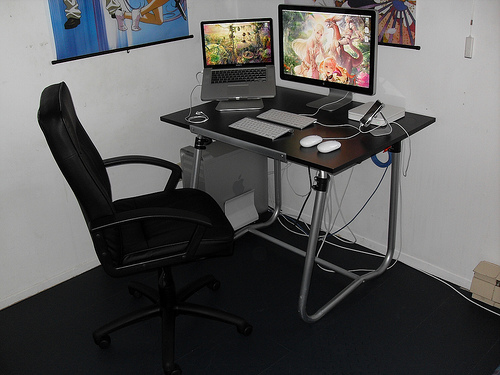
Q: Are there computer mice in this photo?
A: Yes, there is a computer mouse.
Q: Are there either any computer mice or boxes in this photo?
A: Yes, there is a computer mouse.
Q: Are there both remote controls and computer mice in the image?
A: No, there is a computer mouse but no remote controls.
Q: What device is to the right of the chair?
A: The device is a computer mouse.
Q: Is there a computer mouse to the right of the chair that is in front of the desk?
A: Yes, there is a computer mouse to the right of the chair.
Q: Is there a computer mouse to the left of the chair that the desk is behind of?
A: No, the computer mouse is to the right of the chair.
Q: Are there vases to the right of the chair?
A: No, there is a computer mouse to the right of the chair.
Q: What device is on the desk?
A: The device is a computer mouse.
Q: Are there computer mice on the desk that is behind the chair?
A: Yes, there is a computer mouse on the desk.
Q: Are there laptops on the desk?
A: No, there is a computer mouse on the desk.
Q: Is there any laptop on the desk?
A: No, there is a computer mouse on the desk.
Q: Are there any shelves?
A: No, there are no shelves.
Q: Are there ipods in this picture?
A: No, there are no ipods.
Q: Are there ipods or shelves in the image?
A: No, there are no ipods or shelves.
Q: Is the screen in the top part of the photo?
A: Yes, the screen is in the top of the image.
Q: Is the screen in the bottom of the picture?
A: No, the screen is in the top of the image.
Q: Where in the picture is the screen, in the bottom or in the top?
A: The screen is in the top of the image.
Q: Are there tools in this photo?
A: No, there are no tools.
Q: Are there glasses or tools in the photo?
A: No, there are no tools or glasses.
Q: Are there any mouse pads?
A: No, there are no mouse pads.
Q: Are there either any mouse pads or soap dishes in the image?
A: No, there are no mouse pads or soap dishes.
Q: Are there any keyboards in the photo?
A: Yes, there is a keyboard.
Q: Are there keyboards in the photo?
A: Yes, there is a keyboard.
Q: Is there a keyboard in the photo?
A: Yes, there is a keyboard.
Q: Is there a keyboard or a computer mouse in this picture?
A: Yes, there is a keyboard.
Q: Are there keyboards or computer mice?
A: Yes, there is a keyboard.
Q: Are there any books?
A: No, there are no books.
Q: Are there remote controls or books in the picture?
A: No, there are no books or remote controls.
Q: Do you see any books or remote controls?
A: No, there are no books or remote controls.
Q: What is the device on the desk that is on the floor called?
A: The device is a keyboard.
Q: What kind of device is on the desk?
A: The device is a keyboard.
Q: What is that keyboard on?
A: The keyboard is on the desk.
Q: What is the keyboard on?
A: The keyboard is on the desk.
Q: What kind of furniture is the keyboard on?
A: The keyboard is on the desk.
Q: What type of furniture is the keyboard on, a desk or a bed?
A: The keyboard is on a desk.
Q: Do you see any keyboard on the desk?
A: Yes, there is a keyboard on the desk.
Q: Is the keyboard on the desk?
A: Yes, the keyboard is on the desk.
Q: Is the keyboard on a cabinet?
A: No, the keyboard is on the desk.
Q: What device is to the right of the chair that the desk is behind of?
A: The device is a keyboard.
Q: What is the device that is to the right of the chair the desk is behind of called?
A: The device is a keyboard.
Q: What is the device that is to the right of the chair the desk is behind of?
A: The device is a keyboard.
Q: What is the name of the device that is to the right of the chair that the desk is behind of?
A: The device is a keyboard.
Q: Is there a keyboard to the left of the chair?
A: No, the keyboard is to the right of the chair.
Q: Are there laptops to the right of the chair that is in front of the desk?
A: No, there is a keyboard to the right of the chair.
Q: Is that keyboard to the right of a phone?
A: No, the keyboard is to the right of the chair.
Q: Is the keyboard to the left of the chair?
A: No, the keyboard is to the right of the chair.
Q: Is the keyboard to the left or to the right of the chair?
A: The keyboard is to the right of the chair.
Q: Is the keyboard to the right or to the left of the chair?
A: The keyboard is to the right of the chair.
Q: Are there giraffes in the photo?
A: No, there are no giraffes.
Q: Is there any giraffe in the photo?
A: No, there are no giraffes.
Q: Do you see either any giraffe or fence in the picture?
A: No, there are no giraffes or fences.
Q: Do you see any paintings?
A: No, there are no paintings.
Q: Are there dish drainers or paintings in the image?
A: No, there are no paintings or dish drainers.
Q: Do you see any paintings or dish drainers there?
A: No, there are no paintings or dish drainers.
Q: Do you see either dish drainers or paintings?
A: No, there are no paintings or dish drainers.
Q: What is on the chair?
A: The seat is on the chair.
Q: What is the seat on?
A: The seat is on the chair.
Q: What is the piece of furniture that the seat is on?
A: The piece of furniture is a chair.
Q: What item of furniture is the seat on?
A: The seat is on the chair.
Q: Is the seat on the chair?
A: Yes, the seat is on the chair.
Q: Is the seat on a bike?
A: No, the seat is on the chair.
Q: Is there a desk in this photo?
A: Yes, there is a desk.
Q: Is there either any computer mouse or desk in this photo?
A: Yes, there is a desk.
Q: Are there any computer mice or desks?
A: Yes, there is a desk.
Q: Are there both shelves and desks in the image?
A: No, there is a desk but no shelves.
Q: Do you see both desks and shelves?
A: No, there is a desk but no shelves.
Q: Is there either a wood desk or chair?
A: Yes, there is a wood desk.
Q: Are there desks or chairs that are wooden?
A: Yes, the desk is wooden.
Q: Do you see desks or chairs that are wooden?
A: Yes, the desk is wooden.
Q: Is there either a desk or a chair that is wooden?
A: Yes, the desk is wooden.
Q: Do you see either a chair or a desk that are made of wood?
A: Yes, the desk is made of wood.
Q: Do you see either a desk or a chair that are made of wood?
A: Yes, the desk is made of wood.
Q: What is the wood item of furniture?
A: The piece of furniture is a desk.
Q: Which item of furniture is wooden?
A: The piece of furniture is a desk.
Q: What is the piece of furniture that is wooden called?
A: The piece of furniture is a desk.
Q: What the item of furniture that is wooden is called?
A: The piece of furniture is a desk.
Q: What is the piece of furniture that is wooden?
A: The piece of furniture is a desk.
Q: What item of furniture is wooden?
A: The piece of furniture is a desk.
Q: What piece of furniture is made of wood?
A: The piece of furniture is a desk.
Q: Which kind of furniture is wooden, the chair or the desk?
A: The desk is wooden.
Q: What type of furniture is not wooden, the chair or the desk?
A: The chair is not wooden.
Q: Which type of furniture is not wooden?
A: The furniture is a chair.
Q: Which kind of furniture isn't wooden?
A: The furniture is a chair.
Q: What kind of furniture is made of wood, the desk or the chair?
A: The desk is made of wood.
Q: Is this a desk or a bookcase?
A: This is a desk.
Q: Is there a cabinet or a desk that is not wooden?
A: No, there is a desk but it is wooden.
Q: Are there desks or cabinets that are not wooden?
A: No, there is a desk but it is wooden.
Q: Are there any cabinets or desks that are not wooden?
A: No, there is a desk but it is wooden.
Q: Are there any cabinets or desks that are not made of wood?
A: No, there is a desk but it is made of wood.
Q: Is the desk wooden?
A: Yes, the desk is wooden.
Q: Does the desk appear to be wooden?
A: Yes, the desk is wooden.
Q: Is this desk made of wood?
A: Yes, the desk is made of wood.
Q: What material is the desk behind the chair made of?
A: The desk is made of wood.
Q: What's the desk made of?
A: The desk is made of wood.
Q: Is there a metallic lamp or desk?
A: No, there is a desk but it is wooden.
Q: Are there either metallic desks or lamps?
A: No, there is a desk but it is wooden.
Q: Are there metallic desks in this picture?
A: No, there is a desk but it is wooden.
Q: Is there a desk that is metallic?
A: No, there is a desk but it is wooden.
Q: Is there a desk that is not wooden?
A: No, there is a desk but it is wooden.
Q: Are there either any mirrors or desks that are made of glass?
A: No, there is a desk but it is made of wood.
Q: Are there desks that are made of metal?
A: No, there is a desk but it is made of wood.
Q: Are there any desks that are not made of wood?
A: No, there is a desk but it is made of wood.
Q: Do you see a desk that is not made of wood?
A: No, there is a desk but it is made of wood.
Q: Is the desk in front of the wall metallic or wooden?
A: The desk is wooden.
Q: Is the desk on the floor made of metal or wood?
A: The desk is made of wood.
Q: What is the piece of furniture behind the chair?
A: The piece of furniture is a desk.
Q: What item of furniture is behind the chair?
A: The piece of furniture is a desk.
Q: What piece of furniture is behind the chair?
A: The piece of furniture is a desk.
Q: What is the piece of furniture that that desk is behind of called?
A: The piece of furniture is a chair.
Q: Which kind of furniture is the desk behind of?
A: The desk is behind the chair.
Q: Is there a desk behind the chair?
A: Yes, there is a desk behind the chair.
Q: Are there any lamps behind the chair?
A: No, there is a desk behind the chair.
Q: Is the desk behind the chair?
A: Yes, the desk is behind the chair.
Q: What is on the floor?
A: The desk is on the floor.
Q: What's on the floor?
A: The desk is on the floor.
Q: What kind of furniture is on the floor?
A: The piece of furniture is a desk.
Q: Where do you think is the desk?
A: The desk is on the floor.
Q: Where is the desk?
A: The desk is on the floor.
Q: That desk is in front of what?
A: The desk is in front of the wall.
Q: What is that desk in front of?
A: The desk is in front of the wall.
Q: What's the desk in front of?
A: The desk is in front of the wall.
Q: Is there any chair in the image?
A: Yes, there is a chair.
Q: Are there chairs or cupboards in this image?
A: Yes, there is a chair.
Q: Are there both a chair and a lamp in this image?
A: No, there is a chair but no lamps.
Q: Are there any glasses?
A: No, there are no glasses.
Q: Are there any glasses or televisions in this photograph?
A: No, there are no glasses or televisions.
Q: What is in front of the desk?
A: The chair is in front of the desk.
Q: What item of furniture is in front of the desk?
A: The piece of furniture is a chair.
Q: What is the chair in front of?
A: The chair is in front of the desk.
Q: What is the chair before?
A: The chair is in front of the desk.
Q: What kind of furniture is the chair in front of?
A: The chair is in front of the desk.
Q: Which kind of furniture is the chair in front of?
A: The chair is in front of the desk.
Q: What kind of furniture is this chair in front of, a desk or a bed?
A: The chair is in front of a desk.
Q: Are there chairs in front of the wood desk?
A: Yes, there is a chair in front of the desk.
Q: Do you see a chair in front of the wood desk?
A: Yes, there is a chair in front of the desk.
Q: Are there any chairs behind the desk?
A: No, the chair is in front of the desk.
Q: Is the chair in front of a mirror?
A: No, the chair is in front of the desk.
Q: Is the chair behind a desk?
A: No, the chair is in front of a desk.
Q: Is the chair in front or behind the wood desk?
A: The chair is in front of the desk.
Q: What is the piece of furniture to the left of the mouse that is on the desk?
A: The piece of furniture is a chair.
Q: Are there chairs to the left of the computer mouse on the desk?
A: Yes, there is a chair to the left of the computer mouse.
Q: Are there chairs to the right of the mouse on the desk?
A: No, the chair is to the left of the mouse.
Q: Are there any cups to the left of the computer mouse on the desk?
A: No, there is a chair to the left of the computer mouse.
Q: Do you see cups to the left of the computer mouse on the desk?
A: No, there is a chair to the left of the computer mouse.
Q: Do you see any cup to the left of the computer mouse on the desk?
A: No, there is a chair to the left of the computer mouse.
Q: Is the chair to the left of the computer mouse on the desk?
A: Yes, the chair is to the left of the computer mouse.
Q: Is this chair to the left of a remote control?
A: No, the chair is to the left of the computer mouse.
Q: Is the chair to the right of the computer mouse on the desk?
A: No, the chair is to the left of the mouse.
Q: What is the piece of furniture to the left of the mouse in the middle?
A: The piece of furniture is a chair.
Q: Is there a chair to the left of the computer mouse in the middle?
A: Yes, there is a chair to the left of the mouse.